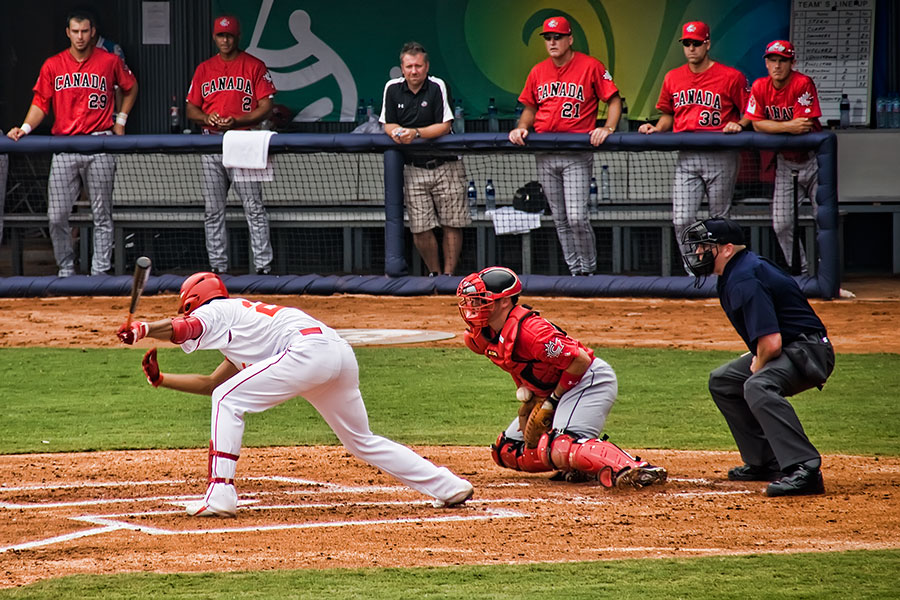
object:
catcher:
[456, 266, 671, 490]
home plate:
[184, 484, 239, 517]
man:
[10, 15, 137, 278]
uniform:
[30, 48, 132, 279]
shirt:
[177, 296, 349, 374]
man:
[378, 43, 472, 278]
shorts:
[400, 160, 471, 233]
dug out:
[0, 128, 839, 297]